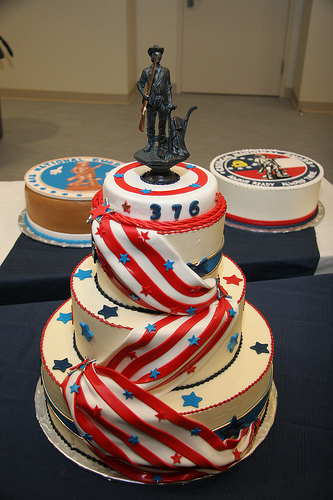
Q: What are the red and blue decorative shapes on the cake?
A: Starts.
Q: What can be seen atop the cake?
A: Figure of man with gun.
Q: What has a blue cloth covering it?
A: Table.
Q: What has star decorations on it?
A: Cake.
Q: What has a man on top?
A: Cake.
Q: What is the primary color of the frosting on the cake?
A: White.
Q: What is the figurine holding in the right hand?
A: A rifle.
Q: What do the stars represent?
A: The states of the union.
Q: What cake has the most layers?
A: The one in front.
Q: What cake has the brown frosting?
A: The cake on the left.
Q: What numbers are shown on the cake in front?
A: 376.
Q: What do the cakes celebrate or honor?
A: The National Guard.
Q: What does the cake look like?
A: Patriotic.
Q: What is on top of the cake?
A: Statue.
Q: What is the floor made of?
A: Concrete.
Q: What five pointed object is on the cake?
A: Stars.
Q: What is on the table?
A: Tablecloth.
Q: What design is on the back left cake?
A: Soldier.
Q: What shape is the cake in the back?
A: Circle.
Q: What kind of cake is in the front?
A: Tiered.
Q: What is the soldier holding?
A: Gun.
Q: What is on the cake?
A: Flag.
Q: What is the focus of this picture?
A: A Cake.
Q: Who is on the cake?
A: A frontiersman.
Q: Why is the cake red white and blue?
A: To represent the us.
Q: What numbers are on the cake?
A: 376.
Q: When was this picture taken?
A: During a celebration.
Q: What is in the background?
A: Two more cakes.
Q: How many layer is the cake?
A: Three.